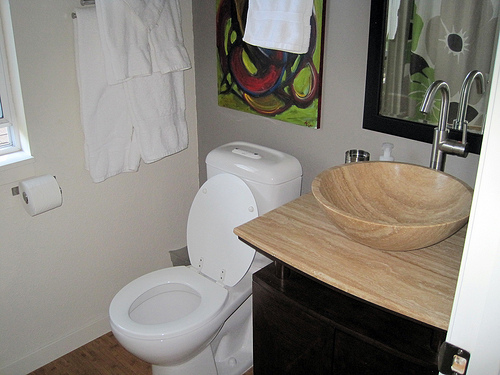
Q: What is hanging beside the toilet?
A: Towels.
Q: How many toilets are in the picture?
A: One.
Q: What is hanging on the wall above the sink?
A: Mirror.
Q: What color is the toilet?
A: White.